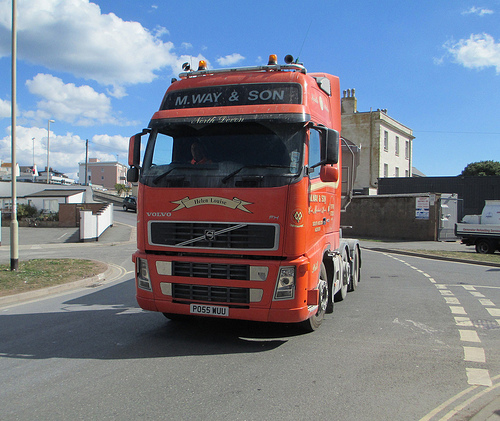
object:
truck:
[126, 54, 363, 331]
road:
[0, 204, 499, 419]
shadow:
[0, 277, 289, 361]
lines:
[460, 282, 499, 325]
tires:
[305, 259, 330, 331]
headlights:
[274, 266, 295, 300]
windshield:
[141, 120, 303, 189]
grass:
[0, 257, 106, 299]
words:
[173, 89, 286, 107]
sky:
[0, 0, 499, 176]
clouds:
[1, 0, 168, 95]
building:
[339, 87, 415, 196]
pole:
[9, 0, 19, 272]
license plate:
[190, 303, 230, 316]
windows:
[383, 130, 389, 155]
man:
[188, 140, 209, 166]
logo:
[170, 195, 255, 214]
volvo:
[146, 211, 172, 217]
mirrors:
[318, 125, 340, 165]